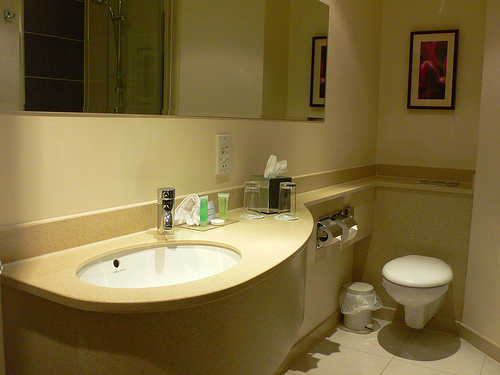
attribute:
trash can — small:
[339, 280, 379, 335]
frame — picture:
[405, 30, 462, 111]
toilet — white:
[378, 246, 454, 333]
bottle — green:
[218, 182, 231, 227]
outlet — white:
[215, 133, 232, 178]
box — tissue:
[245, 173, 293, 218]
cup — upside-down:
[275, 182, 305, 219]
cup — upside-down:
[238, 176, 265, 225]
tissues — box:
[232, 159, 326, 214]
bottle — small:
[197, 196, 209, 229]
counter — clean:
[0, 192, 315, 374]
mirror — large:
[19, 2, 329, 122]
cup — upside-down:
[224, 167, 329, 241]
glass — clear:
[276, 181, 297, 218]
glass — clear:
[241, 174, 261, 219]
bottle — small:
[218, 190, 228, 224]